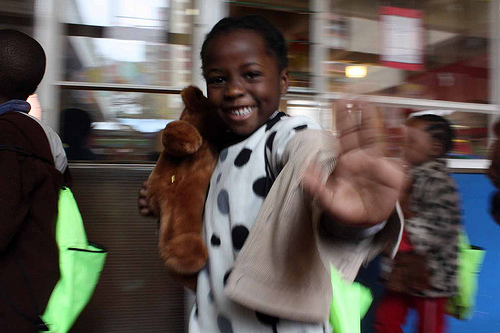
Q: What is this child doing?
A: Waving.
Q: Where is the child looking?
A: At the camera.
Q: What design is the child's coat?
A: Polka dots.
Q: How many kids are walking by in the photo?
A: Three.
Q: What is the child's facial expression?
A: Smiling.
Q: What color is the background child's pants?
A: Red.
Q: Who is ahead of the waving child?
A: A boy.